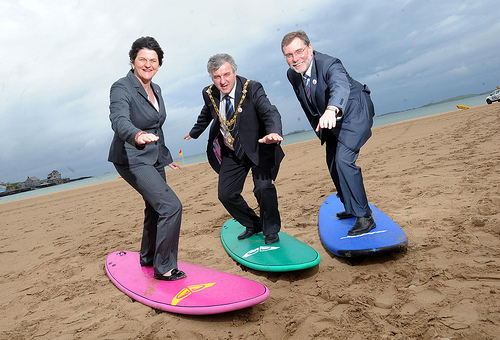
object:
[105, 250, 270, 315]
surfboard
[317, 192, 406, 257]
surfboard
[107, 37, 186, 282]
woman on surfboard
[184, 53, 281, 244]
man on surfboard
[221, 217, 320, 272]
surfboard is green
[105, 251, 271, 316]
pink and yellow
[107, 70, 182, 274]
suit is for business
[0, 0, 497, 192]
clouds in sky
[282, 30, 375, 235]
man has beard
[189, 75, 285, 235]
suit is black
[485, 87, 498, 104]
lifegaurd on beach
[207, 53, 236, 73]
hair is grey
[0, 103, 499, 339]
sand on beach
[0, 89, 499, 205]
water touches sand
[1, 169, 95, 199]
island in water